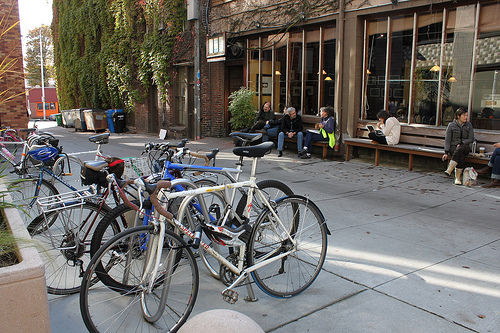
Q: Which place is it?
A: It is a sidewalk.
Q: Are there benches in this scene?
A: Yes, there is a bench.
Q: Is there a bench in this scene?
A: Yes, there is a bench.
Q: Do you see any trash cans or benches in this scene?
A: Yes, there is a bench.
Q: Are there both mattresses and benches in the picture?
A: No, there is a bench but no mattresses.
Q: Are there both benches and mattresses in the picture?
A: No, there is a bench but no mattresses.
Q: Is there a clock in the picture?
A: No, there are no clocks.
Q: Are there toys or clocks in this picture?
A: No, there are no clocks or toys.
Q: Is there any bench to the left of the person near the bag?
A: Yes, there is a bench to the left of the person.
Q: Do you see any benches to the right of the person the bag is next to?
A: No, the bench is to the left of the person.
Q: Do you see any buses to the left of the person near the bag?
A: No, there is a bench to the left of the person.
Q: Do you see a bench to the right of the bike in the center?
A: Yes, there is a bench to the right of the bike.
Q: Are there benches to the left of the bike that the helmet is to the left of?
A: No, the bench is to the right of the bike.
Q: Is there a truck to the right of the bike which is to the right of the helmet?
A: No, there is a bench to the right of the bike.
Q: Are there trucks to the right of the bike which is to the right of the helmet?
A: No, there is a bench to the right of the bike.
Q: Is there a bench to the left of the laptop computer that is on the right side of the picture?
A: Yes, there is a bench to the left of the laptop.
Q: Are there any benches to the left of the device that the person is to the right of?
A: Yes, there is a bench to the left of the laptop.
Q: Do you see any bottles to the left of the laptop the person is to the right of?
A: No, there is a bench to the left of the laptop.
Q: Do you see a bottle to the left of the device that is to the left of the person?
A: No, there is a bench to the left of the laptop.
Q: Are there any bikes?
A: Yes, there is a bike.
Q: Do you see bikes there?
A: Yes, there is a bike.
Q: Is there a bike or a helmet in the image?
A: Yes, there is a bike.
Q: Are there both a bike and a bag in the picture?
A: Yes, there are both a bike and a bag.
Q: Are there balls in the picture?
A: No, there are no balls.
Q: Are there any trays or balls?
A: No, there are no balls or trays.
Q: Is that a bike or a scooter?
A: That is a bike.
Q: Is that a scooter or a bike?
A: That is a bike.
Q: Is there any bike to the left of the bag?
A: Yes, there is a bike to the left of the bag.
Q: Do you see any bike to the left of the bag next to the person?
A: Yes, there is a bike to the left of the bag.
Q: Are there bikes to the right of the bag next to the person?
A: No, the bike is to the left of the bag.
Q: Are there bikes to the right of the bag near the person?
A: No, the bike is to the left of the bag.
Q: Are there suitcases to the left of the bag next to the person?
A: No, there is a bike to the left of the bag.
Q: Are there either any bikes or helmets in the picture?
A: Yes, there is a bike.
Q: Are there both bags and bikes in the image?
A: Yes, there are both a bike and a bag.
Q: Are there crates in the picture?
A: No, there are no crates.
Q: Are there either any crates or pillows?
A: No, there are no crates or pillows.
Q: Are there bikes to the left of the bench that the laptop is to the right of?
A: Yes, there is a bike to the left of the bench.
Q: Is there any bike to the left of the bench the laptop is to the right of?
A: Yes, there is a bike to the left of the bench.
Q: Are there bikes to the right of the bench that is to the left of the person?
A: No, the bike is to the left of the bench.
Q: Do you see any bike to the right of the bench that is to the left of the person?
A: No, the bike is to the left of the bench.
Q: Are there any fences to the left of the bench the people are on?
A: No, there is a bike to the left of the bench.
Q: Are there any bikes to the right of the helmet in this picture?
A: Yes, there is a bike to the right of the helmet.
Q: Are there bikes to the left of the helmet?
A: No, the bike is to the right of the helmet.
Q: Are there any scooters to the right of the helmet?
A: No, there is a bike to the right of the helmet.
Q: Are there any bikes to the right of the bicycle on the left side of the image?
A: Yes, there is a bike to the right of the bicycle.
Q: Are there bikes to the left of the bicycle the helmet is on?
A: No, the bike is to the right of the bicycle.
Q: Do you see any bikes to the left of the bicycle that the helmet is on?
A: No, the bike is to the right of the bicycle.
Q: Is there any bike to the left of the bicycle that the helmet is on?
A: No, the bike is to the right of the bicycle.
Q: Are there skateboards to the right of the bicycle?
A: No, there is a bike to the right of the bicycle.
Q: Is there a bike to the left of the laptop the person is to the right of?
A: Yes, there is a bike to the left of the laptop.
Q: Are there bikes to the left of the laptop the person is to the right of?
A: Yes, there is a bike to the left of the laptop.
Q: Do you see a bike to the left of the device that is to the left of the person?
A: Yes, there is a bike to the left of the laptop.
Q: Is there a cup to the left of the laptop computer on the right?
A: No, there is a bike to the left of the laptop.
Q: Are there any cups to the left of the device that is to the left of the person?
A: No, there is a bike to the left of the laptop.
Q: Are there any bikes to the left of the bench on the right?
A: Yes, there is a bike to the left of the bench.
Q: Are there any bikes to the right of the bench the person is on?
A: No, the bike is to the left of the bench.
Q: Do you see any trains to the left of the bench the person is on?
A: No, there is a bike to the left of the bench.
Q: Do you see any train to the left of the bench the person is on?
A: No, there is a bike to the left of the bench.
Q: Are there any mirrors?
A: No, there are no mirrors.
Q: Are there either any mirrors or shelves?
A: No, there are no mirrors or shelves.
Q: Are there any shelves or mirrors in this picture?
A: No, there are no mirrors or shelves.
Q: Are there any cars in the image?
A: No, there are no cars.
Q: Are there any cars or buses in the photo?
A: No, there are no cars or buses.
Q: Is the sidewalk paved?
A: Yes, the sidewalk is paved.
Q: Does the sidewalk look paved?
A: Yes, the sidewalk is paved.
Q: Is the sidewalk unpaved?
A: No, the sidewalk is paved.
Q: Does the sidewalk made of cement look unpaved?
A: No, the side walk is paved.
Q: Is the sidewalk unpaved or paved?
A: The sidewalk is paved.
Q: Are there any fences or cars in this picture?
A: No, there are no cars or fences.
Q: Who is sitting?
A: The people are sitting.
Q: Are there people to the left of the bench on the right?
A: Yes, there are people to the left of the bench.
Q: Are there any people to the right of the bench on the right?
A: No, the people are to the left of the bench.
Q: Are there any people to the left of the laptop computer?
A: Yes, there are people to the left of the laptop computer.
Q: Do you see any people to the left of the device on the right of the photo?
A: Yes, there are people to the left of the laptop computer.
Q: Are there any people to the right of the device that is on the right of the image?
A: No, the people are to the left of the laptop computer.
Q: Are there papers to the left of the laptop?
A: No, there are people to the left of the laptop.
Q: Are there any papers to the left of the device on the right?
A: No, there are people to the left of the laptop.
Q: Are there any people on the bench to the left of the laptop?
A: Yes, there are people on the bench.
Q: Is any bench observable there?
A: Yes, there is a bench.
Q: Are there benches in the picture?
A: Yes, there is a bench.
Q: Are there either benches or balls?
A: Yes, there is a bench.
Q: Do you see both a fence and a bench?
A: No, there is a bench but no fences.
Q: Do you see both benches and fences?
A: No, there is a bench but no fences.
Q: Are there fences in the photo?
A: No, there are no fences.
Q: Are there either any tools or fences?
A: No, there are no fences or tools.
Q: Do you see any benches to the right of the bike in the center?
A: Yes, there is a bench to the right of the bike.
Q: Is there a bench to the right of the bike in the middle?
A: Yes, there is a bench to the right of the bike.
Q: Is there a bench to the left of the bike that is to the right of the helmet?
A: No, the bench is to the right of the bike.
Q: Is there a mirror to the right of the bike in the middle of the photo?
A: No, there is a bench to the right of the bike.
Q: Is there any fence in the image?
A: No, there are no fences.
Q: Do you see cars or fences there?
A: No, there are no fences or cars.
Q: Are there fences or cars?
A: No, there are no fences or cars.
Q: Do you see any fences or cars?
A: No, there are no fences or cars.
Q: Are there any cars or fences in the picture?
A: No, there are no fences or cars.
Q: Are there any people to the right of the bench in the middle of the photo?
A: Yes, there is a person to the right of the bench.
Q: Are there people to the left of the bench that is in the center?
A: No, the person is to the right of the bench.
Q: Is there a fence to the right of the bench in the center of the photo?
A: No, there is a person to the right of the bench.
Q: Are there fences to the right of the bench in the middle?
A: No, there is a person to the right of the bench.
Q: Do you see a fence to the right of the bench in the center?
A: No, there is a person to the right of the bench.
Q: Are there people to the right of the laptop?
A: Yes, there is a person to the right of the laptop.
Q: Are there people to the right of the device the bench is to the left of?
A: Yes, there is a person to the right of the laptop.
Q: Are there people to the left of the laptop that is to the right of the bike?
A: No, the person is to the right of the laptop.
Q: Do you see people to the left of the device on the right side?
A: No, the person is to the right of the laptop.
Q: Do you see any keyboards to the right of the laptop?
A: No, there is a person to the right of the laptop.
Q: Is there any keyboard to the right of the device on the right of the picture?
A: No, there is a person to the right of the laptop.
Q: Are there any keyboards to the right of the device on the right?
A: No, there is a person to the right of the laptop.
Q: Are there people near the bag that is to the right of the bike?
A: Yes, there is a person near the bag.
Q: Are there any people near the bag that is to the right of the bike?
A: Yes, there is a person near the bag.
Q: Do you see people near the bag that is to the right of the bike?
A: Yes, there is a person near the bag.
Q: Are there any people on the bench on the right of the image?
A: Yes, there is a person on the bench.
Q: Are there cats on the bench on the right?
A: No, there is a person on the bench.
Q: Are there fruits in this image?
A: No, there are no fruits.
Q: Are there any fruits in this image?
A: No, there are no fruits.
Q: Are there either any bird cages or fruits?
A: No, there are no fruits or bird cages.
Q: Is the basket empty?
A: Yes, the basket is empty.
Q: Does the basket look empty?
A: Yes, the basket is empty.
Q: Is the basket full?
A: No, the basket is empty.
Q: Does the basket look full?
A: No, the basket is empty.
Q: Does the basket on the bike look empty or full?
A: The basket is empty.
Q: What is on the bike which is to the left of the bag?
A: The basket is on the bike.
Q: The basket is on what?
A: The basket is on the bike.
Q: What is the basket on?
A: The basket is on the bike.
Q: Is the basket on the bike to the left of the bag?
A: Yes, the basket is on the bike.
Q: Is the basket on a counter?
A: No, the basket is on the bike.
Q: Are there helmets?
A: Yes, there is a helmet.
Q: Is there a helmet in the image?
A: Yes, there is a helmet.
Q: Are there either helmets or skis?
A: Yes, there is a helmet.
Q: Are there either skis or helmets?
A: Yes, there is a helmet.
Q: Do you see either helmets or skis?
A: Yes, there is a helmet.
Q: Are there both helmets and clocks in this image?
A: No, there is a helmet but no clocks.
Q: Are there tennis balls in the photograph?
A: No, there are no tennis balls.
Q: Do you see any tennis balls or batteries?
A: No, there are no tennis balls or batteries.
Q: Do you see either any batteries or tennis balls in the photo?
A: No, there are no tennis balls or batteries.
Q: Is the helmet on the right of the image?
A: No, the helmet is on the left of the image.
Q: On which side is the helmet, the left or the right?
A: The helmet is on the left of the image.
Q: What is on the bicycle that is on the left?
A: The helmet is on the bicycle.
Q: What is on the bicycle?
A: The helmet is on the bicycle.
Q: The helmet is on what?
A: The helmet is on the bicycle.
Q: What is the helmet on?
A: The helmet is on the bicycle.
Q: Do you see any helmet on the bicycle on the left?
A: Yes, there is a helmet on the bicycle.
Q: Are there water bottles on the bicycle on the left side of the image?
A: No, there is a helmet on the bicycle.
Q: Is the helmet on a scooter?
A: No, the helmet is on the bicycle.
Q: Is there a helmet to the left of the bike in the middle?
A: Yes, there is a helmet to the left of the bike.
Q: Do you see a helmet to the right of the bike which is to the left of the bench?
A: No, the helmet is to the left of the bike.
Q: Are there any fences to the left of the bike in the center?
A: No, there is a helmet to the left of the bike.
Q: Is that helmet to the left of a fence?
A: No, the helmet is to the left of the bike.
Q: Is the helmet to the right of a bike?
A: No, the helmet is to the left of a bike.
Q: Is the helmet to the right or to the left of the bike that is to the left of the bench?
A: The helmet is to the left of the bike.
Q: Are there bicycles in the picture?
A: Yes, there is a bicycle.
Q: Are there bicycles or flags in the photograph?
A: Yes, there is a bicycle.